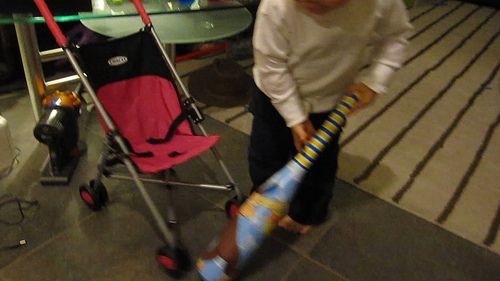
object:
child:
[238, 0, 414, 236]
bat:
[192, 90, 359, 280]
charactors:
[201, 181, 284, 281]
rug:
[380, 0, 500, 237]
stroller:
[24, 0, 252, 278]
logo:
[103, 55, 130, 67]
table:
[0, 0, 258, 46]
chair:
[28, 0, 255, 274]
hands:
[288, 117, 321, 155]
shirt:
[246, 0, 412, 140]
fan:
[29, 102, 91, 186]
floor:
[0, 0, 495, 281]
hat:
[187, 58, 255, 109]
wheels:
[76, 184, 105, 212]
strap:
[116, 111, 196, 157]